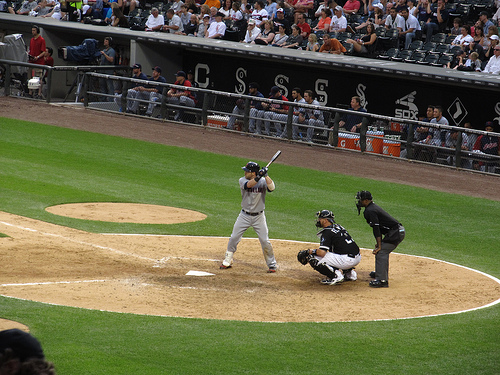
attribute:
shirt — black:
[362, 204, 402, 238]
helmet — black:
[314, 208, 326, 228]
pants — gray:
[372, 232, 401, 279]